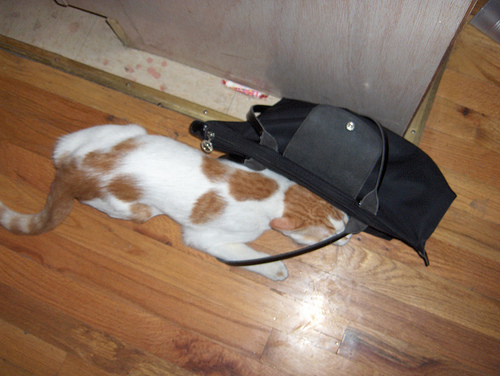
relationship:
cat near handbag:
[0, 124, 352, 282] [187, 96, 455, 268]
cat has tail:
[0, 124, 352, 282] [7, 167, 88, 255]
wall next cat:
[3, 9, 476, 184] [0, 124, 352, 282]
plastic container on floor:
[467, 0, 497, 48] [4, 20, 496, 372]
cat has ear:
[0, 124, 352, 282] [266, 217, 303, 235]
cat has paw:
[0, 124, 352, 282] [261, 257, 287, 279]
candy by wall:
[168, 40, 315, 134] [143, 15, 467, 180]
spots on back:
[186, 152, 273, 231] [144, 138, 299, 222]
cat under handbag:
[0, 124, 352, 282] [187, 96, 455, 268]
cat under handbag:
[0, 124, 352, 282] [208, 86, 447, 246]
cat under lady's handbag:
[0, 124, 352, 282] [180, 92, 461, 268]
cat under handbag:
[0, 124, 352, 282] [187, 57, 462, 285]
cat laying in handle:
[0, 124, 352, 282] [193, 154, 357, 270]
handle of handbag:
[193, 154, 357, 270] [187, 96, 455, 268]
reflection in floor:
[269, 268, 356, 362] [4, 20, 496, 372]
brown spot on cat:
[228, 164, 279, 199] [0, 124, 352, 282]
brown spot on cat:
[198, 150, 228, 185] [0, 124, 352, 282]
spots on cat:
[186, 187, 232, 227] [0, 124, 352, 282]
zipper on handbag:
[256, 146, 373, 228] [187, 96, 455, 268]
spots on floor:
[119, 50, 175, 91] [42, 72, 499, 351]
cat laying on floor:
[59, 115, 336, 275] [113, 282, 240, 361]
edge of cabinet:
[46, 0, 153, 58] [76, 4, 469, 131]